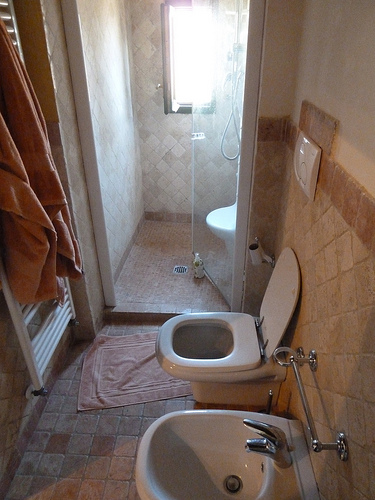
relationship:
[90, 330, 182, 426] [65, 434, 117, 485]
towel on floor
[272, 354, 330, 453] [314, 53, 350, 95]
metal bar on wall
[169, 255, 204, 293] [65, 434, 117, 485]
drain in floor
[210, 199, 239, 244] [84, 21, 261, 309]
bidet in shower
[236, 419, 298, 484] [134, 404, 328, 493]
faucet on sink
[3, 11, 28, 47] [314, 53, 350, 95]
towel rack on wall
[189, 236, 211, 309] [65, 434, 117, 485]
bottle on floor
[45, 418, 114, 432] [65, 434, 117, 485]
tiles on floor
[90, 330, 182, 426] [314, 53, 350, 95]
towel on wall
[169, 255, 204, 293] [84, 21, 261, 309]
drain in shower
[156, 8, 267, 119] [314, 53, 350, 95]
window in wall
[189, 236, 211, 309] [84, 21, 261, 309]
bottle in shower